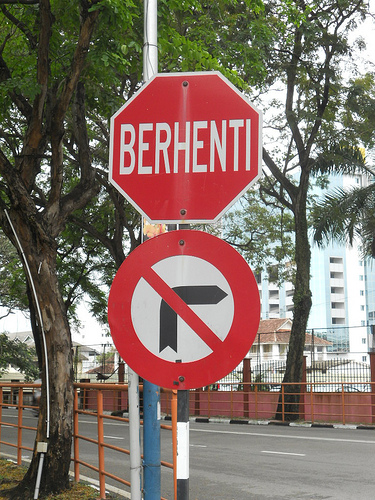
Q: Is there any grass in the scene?
A: Yes, there is grass.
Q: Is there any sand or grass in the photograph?
A: Yes, there is grass.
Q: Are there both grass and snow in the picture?
A: No, there is grass but no snow.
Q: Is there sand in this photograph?
A: No, there is no sand.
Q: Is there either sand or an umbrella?
A: No, there are no sand or umbrellas.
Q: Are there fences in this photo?
A: Yes, there is a fence.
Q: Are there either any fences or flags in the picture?
A: Yes, there is a fence.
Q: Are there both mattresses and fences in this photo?
A: No, there is a fence but no mattresses.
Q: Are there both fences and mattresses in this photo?
A: No, there is a fence but no mattresses.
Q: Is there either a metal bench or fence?
A: Yes, there is a metal fence.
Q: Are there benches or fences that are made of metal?
A: Yes, the fence is made of metal.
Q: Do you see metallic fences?
A: Yes, there is a metal fence.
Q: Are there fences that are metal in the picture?
A: Yes, there is a metal fence.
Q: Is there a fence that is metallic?
A: Yes, there is a fence that is metallic.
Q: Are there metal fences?
A: Yes, there is a fence that is made of metal.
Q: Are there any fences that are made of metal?
A: Yes, there is a fence that is made of metal.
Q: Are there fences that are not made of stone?
A: Yes, there is a fence that is made of metal.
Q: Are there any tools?
A: No, there are no tools.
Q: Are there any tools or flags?
A: No, there are no tools or flags.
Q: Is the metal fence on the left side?
A: Yes, the fence is on the left of the image.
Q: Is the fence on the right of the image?
A: No, the fence is on the left of the image.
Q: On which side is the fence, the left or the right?
A: The fence is on the left of the image.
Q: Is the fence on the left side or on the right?
A: The fence is on the left of the image.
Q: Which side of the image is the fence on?
A: The fence is on the left of the image.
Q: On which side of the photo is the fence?
A: The fence is on the left of the image.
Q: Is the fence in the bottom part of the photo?
A: Yes, the fence is in the bottom of the image.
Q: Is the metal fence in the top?
A: No, the fence is in the bottom of the image.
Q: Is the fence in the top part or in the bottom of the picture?
A: The fence is in the bottom of the image.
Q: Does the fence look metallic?
A: Yes, the fence is metallic.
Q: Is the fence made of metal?
A: Yes, the fence is made of metal.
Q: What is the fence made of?
A: The fence is made of metal.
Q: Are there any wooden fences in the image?
A: No, there is a fence but it is metallic.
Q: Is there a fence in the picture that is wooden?
A: No, there is a fence but it is metallic.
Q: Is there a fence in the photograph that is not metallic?
A: No, there is a fence but it is metallic.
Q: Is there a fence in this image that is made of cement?
A: No, there is a fence but it is made of metal.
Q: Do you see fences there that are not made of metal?
A: No, there is a fence but it is made of metal.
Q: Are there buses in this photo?
A: No, there are no buses.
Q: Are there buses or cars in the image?
A: No, there are no buses or cars.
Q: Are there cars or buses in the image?
A: No, there are no buses or cars.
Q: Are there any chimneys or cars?
A: No, there are no cars or chimneys.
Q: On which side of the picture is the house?
A: The house is on the right of the image.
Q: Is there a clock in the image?
A: No, there are no clocks.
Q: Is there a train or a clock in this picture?
A: No, there are no clocks or trains.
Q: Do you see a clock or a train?
A: No, there are no clocks or trains.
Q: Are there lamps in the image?
A: No, there are no lamps.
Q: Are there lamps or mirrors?
A: No, there are no lamps or mirrors.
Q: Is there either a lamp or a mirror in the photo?
A: No, there are no lamps or mirrors.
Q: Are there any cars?
A: No, there are no cars.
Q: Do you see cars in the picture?
A: No, there are no cars.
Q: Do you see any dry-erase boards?
A: No, there are no dry-erase boards.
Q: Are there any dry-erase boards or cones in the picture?
A: No, there are no dry-erase boards or cones.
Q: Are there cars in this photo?
A: No, there are no cars.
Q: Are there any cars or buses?
A: No, there are no cars or buses.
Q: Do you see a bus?
A: No, there are no buses.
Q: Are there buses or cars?
A: No, there are no buses or cars.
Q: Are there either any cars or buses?
A: No, there are no buses or cars.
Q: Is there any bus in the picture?
A: No, there are no buses.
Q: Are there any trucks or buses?
A: No, there are no buses or trucks.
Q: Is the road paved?
A: Yes, the road is paved.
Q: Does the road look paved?
A: Yes, the road is paved.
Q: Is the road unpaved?
A: No, the road is paved.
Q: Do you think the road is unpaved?
A: No, the road is paved.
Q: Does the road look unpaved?
A: No, the road is paved.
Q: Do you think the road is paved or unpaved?
A: The road is paved.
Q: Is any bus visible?
A: No, there are no buses.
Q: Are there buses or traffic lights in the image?
A: No, there are no buses or traffic lights.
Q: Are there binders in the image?
A: No, there are no binders.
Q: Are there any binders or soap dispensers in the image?
A: No, there are no binders or soap dispensers.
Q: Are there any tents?
A: No, there are no tents.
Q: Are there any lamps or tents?
A: No, there are no tents or lamps.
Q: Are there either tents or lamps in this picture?
A: No, there are no tents or lamps.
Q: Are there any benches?
A: No, there are no benches.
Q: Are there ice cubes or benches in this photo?
A: No, there are no benches or ice cubes.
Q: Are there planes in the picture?
A: No, there are no planes.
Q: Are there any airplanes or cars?
A: No, there are no airplanes or cars.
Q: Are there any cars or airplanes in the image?
A: No, there are no airplanes or cars.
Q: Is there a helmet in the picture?
A: No, there are no helmets.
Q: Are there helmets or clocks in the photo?
A: No, there are no helmets or clocks.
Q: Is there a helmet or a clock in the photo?
A: No, there are no helmets or clocks.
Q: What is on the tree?
A: The wire is on the tree.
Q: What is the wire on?
A: The wire is on the tree.